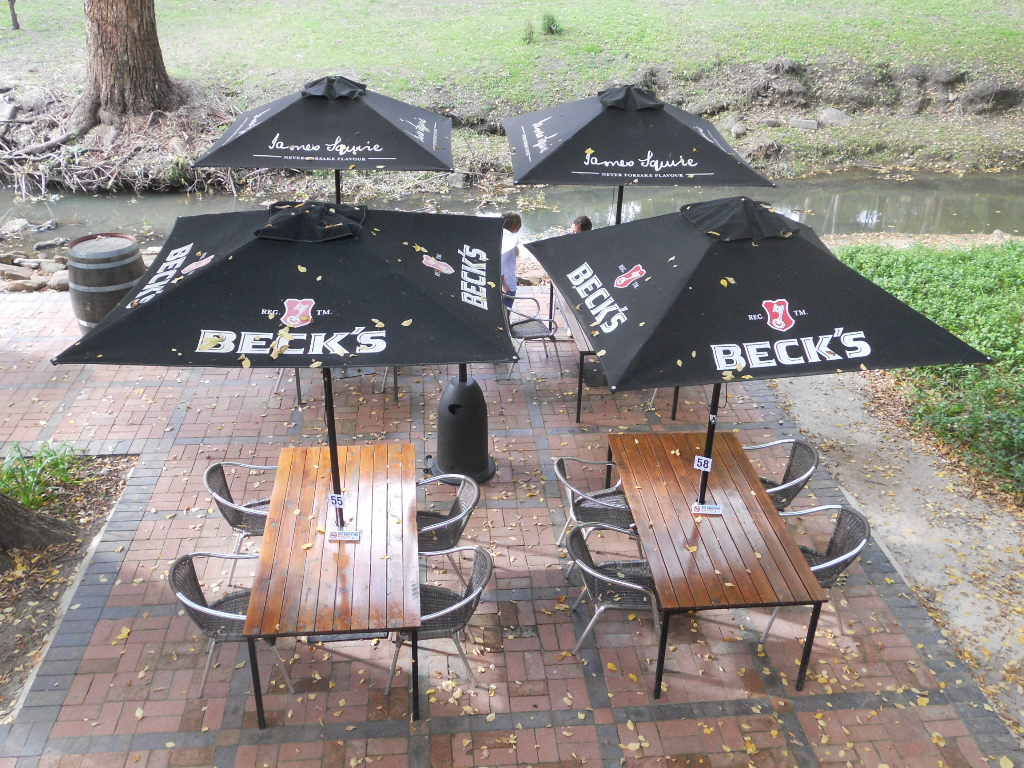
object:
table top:
[246, 442, 426, 640]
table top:
[607, 427, 834, 618]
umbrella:
[522, 195, 987, 394]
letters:
[194, 329, 237, 356]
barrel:
[65, 231, 146, 338]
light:
[854, 202, 883, 226]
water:
[2, 181, 1024, 251]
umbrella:
[52, 196, 513, 371]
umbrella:
[498, 83, 778, 189]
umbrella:
[190, 71, 457, 173]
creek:
[0, 165, 1021, 253]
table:
[605, 430, 826, 700]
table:
[238, 443, 427, 731]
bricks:
[132, 423, 156, 441]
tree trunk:
[68, 0, 186, 116]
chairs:
[199, 456, 274, 586]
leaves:
[109, 623, 136, 647]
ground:
[0, 0, 1024, 186]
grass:
[849, 250, 1024, 489]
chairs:
[167, 552, 295, 700]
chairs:
[379, 546, 495, 698]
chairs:
[562, 521, 662, 659]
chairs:
[758, 504, 870, 645]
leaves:
[699, 724, 722, 741]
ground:
[0, 238, 1024, 768]